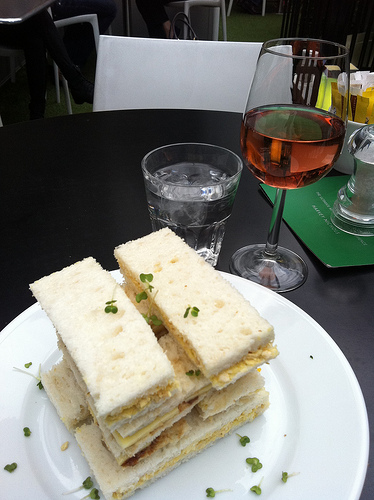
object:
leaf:
[141, 313, 163, 326]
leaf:
[183, 306, 200, 318]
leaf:
[246, 457, 262, 471]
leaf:
[206, 487, 216, 496]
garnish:
[183, 306, 199, 318]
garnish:
[105, 300, 119, 314]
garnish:
[136, 273, 155, 302]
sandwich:
[28, 227, 277, 498]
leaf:
[104, 299, 117, 314]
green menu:
[260, 173, 373, 269]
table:
[0, 109, 374, 498]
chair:
[93, 34, 294, 113]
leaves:
[236, 433, 250, 447]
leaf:
[135, 273, 153, 303]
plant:
[282, 471, 287, 483]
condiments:
[332, 81, 374, 123]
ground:
[2, 10, 299, 124]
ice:
[149, 162, 231, 266]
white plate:
[0, 267, 370, 499]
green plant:
[250, 485, 262, 494]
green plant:
[4, 461, 17, 471]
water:
[148, 162, 238, 266]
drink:
[240, 104, 346, 190]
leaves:
[185, 370, 200, 376]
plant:
[73, 476, 100, 497]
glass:
[140, 143, 243, 267]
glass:
[228, 38, 350, 292]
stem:
[264, 187, 285, 255]